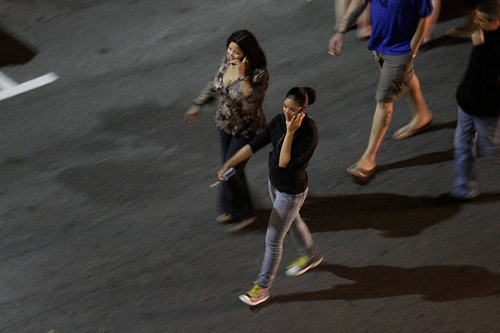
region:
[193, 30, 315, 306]
these are two women walking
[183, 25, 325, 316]
the women are holding cell phones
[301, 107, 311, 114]
the cell phone is back in color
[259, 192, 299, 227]
the woman has grey jeans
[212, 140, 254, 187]
the womans right hand is in front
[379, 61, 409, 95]
the man is wearing shorts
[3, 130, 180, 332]
the road is tarmacked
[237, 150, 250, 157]
the woman is light skinned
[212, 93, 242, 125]
the womans blouse is flowered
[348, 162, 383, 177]
the man has sandals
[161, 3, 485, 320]
Picture of people walking.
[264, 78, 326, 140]
Woman on right has dark hair.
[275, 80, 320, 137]
Woman on right has hair pulled up.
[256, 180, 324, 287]
Pair of light colored pants.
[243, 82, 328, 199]
Woman on right talking on cell phone.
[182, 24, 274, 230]
Woman on left has long black hair.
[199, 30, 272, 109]
Woman on left talking on cell phone.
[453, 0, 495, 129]
Man in black shirt.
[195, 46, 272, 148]
Woman on left has long sleeve shirt.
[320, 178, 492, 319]
Shadows of women on street.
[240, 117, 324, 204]
the jacket is black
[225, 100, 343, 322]
the girl is wearing shoes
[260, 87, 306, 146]
the woman is holding a phone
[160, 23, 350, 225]
two women talking on the phone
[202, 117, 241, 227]
the pants are black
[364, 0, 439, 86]
the shirt is blue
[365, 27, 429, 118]
the shorts are brown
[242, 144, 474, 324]
shadows on the ground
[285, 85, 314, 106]
the hair is black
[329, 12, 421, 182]
the man is wearing shorts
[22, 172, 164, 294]
part f a road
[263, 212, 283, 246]
section of a jeans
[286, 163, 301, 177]
part of a black sweater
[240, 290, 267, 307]
a shoe on the left leg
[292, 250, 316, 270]
a shoe on the right shoe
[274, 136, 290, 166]
left arm of a lady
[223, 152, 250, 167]
right arm of a lady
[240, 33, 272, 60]
hair of a lady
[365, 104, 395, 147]
left leg of a man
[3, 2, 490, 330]
A street for cars to drive down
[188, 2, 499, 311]
A group of people walking down the street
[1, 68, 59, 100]
A white line painted on the street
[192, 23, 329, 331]
Two women talking on their cellphones.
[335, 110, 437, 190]
A pair of sandals on the man's feet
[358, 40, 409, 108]
A pair of shorts on the man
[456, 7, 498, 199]
A man walking down the road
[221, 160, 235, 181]
A small purse in the woman's hand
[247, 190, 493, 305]
Two shadows in the road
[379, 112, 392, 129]
A tattoo on the man's leg